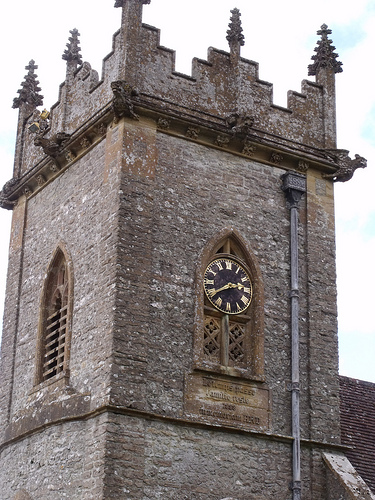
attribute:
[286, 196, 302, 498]
pipe — gray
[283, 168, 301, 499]
pole — silver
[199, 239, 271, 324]
clock — large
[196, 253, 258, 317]
clock — black, gold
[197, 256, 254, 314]
clock — old roman, analog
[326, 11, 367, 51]
sky — blue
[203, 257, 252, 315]
clock face — round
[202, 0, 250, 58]
statue — on right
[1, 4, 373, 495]
tower — large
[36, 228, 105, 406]
window — decorative